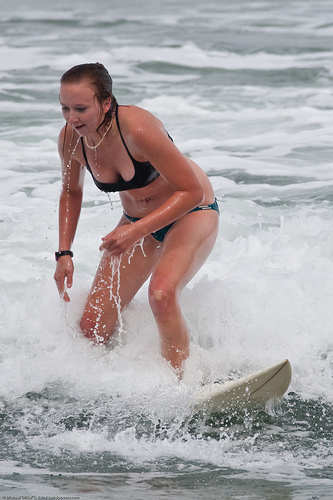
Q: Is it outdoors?
A: Yes, it is outdoors.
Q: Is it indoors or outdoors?
A: It is outdoors.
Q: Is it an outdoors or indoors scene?
A: It is outdoors.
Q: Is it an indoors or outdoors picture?
A: It is outdoors.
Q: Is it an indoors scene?
A: No, it is outdoors.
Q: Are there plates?
A: No, there are no plates.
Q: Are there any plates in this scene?
A: No, there are no plates.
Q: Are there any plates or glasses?
A: No, there are no plates or glasses.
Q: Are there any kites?
A: No, there are no kites.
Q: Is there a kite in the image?
A: No, there are no kites.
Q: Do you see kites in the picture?
A: No, there are no kites.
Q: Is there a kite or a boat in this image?
A: No, there are no kites or boats.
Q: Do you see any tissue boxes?
A: No, there are no tissue boxes.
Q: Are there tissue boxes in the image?
A: No, there are no tissue boxes.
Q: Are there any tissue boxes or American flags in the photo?
A: No, there are no tissue boxes or American flags.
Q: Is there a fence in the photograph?
A: No, there are no fences.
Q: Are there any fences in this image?
A: No, there are no fences.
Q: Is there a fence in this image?
A: No, there are no fences.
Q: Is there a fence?
A: No, there are no fences.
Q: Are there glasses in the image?
A: No, there are no glasses.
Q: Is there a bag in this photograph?
A: No, there are no bags.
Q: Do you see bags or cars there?
A: No, there are no bags or cars.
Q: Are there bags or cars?
A: No, there are no bags or cars.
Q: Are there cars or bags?
A: No, there are no bags or cars.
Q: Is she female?
A: Yes, the person is female.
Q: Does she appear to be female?
A: Yes, the person is female.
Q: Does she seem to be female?
A: Yes, the person is female.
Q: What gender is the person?
A: The person is female.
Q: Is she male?
A: No, the person is female.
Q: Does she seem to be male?
A: No, the person is female.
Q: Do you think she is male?
A: No, the person is female.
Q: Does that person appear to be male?
A: No, the person is female.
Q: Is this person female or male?
A: The person is female.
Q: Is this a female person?
A: Yes, this is a female person.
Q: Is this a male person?
A: No, this is a female person.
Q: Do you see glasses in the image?
A: No, there are no glasses.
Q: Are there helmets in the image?
A: No, there are no helmets.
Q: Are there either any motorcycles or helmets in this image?
A: No, there are no helmets or motorcycles.